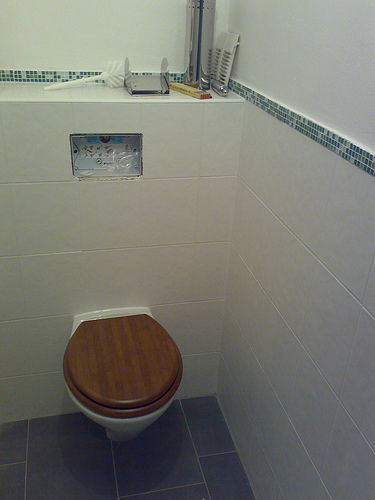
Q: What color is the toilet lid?
A: Brown.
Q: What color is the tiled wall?
A: White.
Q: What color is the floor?
A: Blue.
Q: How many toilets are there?
A: One.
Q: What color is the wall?
A: White.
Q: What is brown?
A: Toilet cover.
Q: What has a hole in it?
A: Wall.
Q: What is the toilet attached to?
A: Wall.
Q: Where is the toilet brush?
A: On the shelf.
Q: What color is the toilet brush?
A: White.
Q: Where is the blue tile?
A: Floor.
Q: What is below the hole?
A: Toilet.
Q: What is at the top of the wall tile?
A: Border.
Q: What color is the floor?
A: Gray.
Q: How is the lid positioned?
A: Down.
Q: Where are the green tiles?
A: Midway up the wall.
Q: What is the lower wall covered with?
A: Tiles.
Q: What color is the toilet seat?
A: Brown.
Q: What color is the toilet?
A: White.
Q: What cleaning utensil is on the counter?
A: Brush.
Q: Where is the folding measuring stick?
A: Countertop.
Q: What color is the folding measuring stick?
A: Yellow and red.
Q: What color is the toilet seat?
A: Brown.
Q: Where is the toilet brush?
A: On a shelf.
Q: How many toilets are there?
A: One.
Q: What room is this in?
A: Bathroom.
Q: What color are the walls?
A: White.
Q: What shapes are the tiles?
A: Rectangular.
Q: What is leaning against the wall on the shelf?
A: A vent cover.